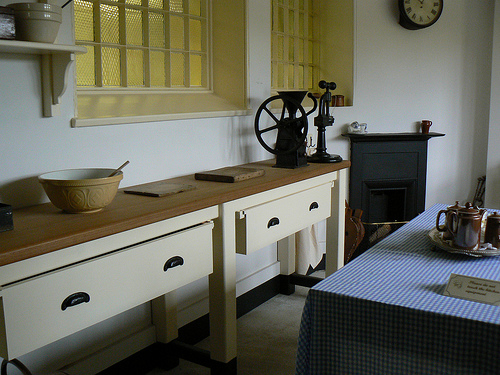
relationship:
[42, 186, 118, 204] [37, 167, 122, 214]
design on bowl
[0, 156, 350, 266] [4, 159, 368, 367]
top on buffet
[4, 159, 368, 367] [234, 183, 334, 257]
buffet has drawer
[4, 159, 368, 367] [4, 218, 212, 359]
buffet has drawer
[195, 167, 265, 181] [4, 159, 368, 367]
board on buffet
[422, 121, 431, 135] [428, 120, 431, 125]
cup has handle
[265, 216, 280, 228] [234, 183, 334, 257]
handle on drawer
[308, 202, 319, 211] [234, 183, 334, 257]
handle on drawer